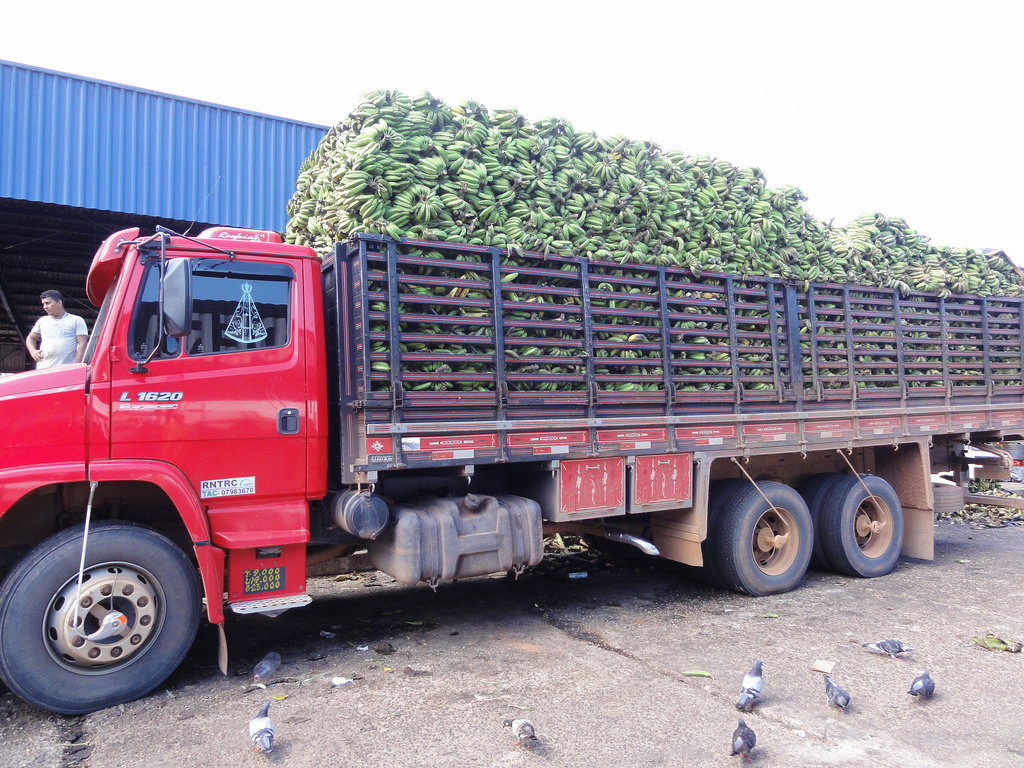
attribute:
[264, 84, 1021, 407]
banana — large, green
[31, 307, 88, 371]
shirt — white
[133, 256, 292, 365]
window — driver side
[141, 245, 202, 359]
mirror — large, driver side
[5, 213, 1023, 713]
truck — red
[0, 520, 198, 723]
tire — black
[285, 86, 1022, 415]
bananas — piled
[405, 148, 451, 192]
banana bunch — large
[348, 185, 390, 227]
banana bunch — large